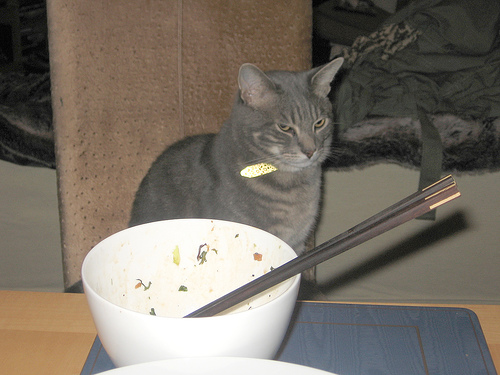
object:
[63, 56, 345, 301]
cat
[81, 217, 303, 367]
bowl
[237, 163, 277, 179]
collar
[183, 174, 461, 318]
chop stick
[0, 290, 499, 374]
table